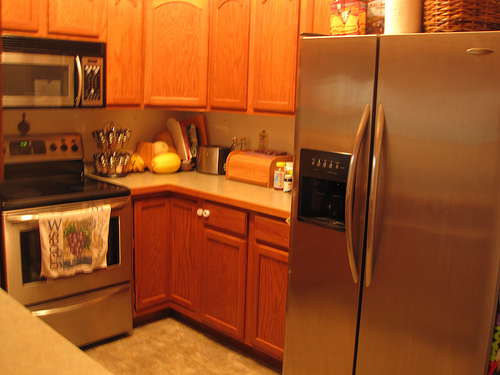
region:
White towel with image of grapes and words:
[35, 203, 115, 280]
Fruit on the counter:
[129, 130, 181, 170]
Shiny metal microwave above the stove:
[0, 43, 107, 113]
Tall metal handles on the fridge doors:
[344, 99, 381, 286]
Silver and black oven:
[0, 135, 139, 349]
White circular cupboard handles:
[196, 208, 210, 223]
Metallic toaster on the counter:
[193, 142, 223, 178]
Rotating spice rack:
[88, 120, 135, 179]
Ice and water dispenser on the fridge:
[298, 143, 353, 228]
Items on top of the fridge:
[324, 2, 496, 35]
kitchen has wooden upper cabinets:
[18, 3, 323, 141]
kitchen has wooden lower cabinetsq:
[89, 131, 322, 371]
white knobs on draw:
[115, 155, 262, 264]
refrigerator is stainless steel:
[280, 13, 495, 372]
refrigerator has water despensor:
[256, 10, 409, 327]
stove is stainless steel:
[0, 123, 156, 350]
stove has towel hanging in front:
[11, 134, 141, 340]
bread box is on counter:
[206, 130, 291, 222]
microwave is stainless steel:
[5, 29, 125, 136]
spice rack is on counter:
[86, 115, 156, 210]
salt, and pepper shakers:
[100, 129, 122, 176]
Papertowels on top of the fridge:
[388, 18, 414, 43]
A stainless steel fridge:
[273, 276, 317, 318]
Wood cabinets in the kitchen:
[232, 323, 252, 356]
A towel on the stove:
[91, 244, 120, 281]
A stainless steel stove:
[115, 301, 140, 334]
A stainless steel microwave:
[69, 89, 101, 112]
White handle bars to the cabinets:
[201, 206, 216, 231]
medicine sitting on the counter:
[278, 168, 293, 196]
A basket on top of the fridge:
[445, 5, 478, 44]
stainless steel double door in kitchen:
[279, 19, 499, 374]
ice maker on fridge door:
[278, 121, 377, 241]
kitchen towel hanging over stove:
[12, 200, 123, 281]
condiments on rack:
[81, 117, 149, 192]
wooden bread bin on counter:
[218, 140, 291, 203]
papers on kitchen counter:
[155, 108, 222, 176]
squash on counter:
[141, 134, 181, 184]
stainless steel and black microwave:
[0, 29, 127, 129]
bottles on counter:
[261, 155, 304, 200]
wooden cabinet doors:
[132, 179, 319, 364]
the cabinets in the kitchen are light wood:
[10, 2, 399, 367]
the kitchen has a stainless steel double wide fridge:
[273, 28, 498, 371]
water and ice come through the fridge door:
[291, 130, 365, 250]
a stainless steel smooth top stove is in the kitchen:
[0, 135, 132, 359]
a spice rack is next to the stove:
[91, 118, 134, 180]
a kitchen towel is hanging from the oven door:
[33, 202, 115, 281]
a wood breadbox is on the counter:
[223, 145, 280, 186]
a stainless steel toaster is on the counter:
[194, 140, 227, 178]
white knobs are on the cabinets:
[191, 205, 216, 221]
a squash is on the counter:
[148, 148, 183, 175]